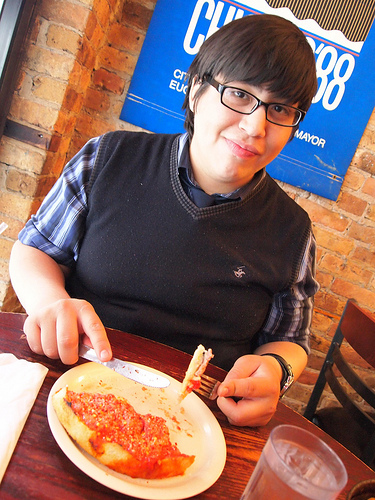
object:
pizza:
[50, 384, 196, 479]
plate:
[46, 360, 227, 498]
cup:
[238, 422, 348, 498]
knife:
[78, 343, 171, 388]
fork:
[193, 372, 222, 400]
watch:
[259, 352, 294, 402]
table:
[0, 310, 374, 498]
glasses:
[203, 73, 307, 128]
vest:
[66, 130, 312, 372]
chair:
[303, 297, 375, 472]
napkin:
[0, 352, 49, 480]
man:
[8, 14, 320, 428]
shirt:
[18, 128, 320, 373]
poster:
[118, 0, 374, 202]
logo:
[233, 265, 246, 280]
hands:
[23, 298, 114, 365]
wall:
[0, 0, 374, 376]